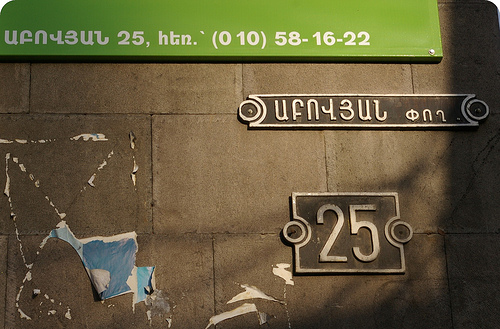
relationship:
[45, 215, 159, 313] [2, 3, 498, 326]
paper on surface of wall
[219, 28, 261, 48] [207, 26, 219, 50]
0 10 inside of parenthesis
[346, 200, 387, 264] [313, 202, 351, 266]
5 next to 2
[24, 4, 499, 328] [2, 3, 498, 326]
shadow on top of wall